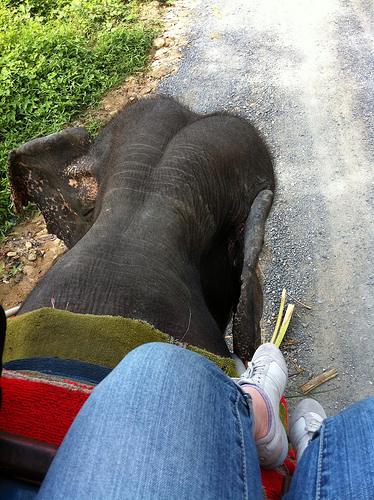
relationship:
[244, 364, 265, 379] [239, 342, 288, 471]
shoelaces on foot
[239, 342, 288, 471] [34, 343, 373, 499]
foot of person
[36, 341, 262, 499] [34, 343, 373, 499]
pant leg of person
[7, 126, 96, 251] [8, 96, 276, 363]
ear of elephant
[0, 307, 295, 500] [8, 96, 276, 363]
rug on elephant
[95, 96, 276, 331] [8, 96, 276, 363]
head of elephant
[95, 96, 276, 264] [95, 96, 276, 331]
head of head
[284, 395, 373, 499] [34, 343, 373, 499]
pant leg of person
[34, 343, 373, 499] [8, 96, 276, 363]
person sitting on elephant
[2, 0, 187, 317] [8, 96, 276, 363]
dirt to left of elephant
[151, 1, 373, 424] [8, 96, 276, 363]
road in front of elephant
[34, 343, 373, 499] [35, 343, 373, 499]
person wearing jeans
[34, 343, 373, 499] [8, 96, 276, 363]
person riding on elephant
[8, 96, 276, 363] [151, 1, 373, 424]
elephant walking down road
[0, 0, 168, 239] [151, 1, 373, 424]
grass on side of road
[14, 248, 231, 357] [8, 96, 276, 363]
back of elephant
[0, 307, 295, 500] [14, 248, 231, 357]
rug on back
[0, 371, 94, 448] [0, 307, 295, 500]
stripe on rug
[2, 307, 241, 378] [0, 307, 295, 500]
stripe on rug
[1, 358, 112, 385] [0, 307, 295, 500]
stripe on rug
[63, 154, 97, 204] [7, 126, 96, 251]
area behind ear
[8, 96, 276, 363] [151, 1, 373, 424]
elephant on road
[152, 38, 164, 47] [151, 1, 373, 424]
rock beside road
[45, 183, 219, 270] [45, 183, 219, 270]
neck of neck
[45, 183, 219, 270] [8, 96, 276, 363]
neck of elephant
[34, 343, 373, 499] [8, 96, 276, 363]
person riding on back of elephant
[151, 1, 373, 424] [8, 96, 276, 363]
road for elephant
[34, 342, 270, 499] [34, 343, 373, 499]
leg of person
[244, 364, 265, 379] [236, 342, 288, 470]
shoelaces on tennis shoe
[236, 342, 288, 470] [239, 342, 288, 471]
tennis shoe on foot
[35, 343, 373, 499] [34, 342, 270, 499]
jeans on leg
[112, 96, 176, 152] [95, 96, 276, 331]
bump on top of head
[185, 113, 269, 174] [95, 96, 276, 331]
bump on top of head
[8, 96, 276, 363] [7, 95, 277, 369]
elephant has skin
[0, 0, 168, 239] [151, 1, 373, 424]
grass next to road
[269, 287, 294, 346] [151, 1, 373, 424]
straw on road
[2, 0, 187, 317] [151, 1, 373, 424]
dirt next to road